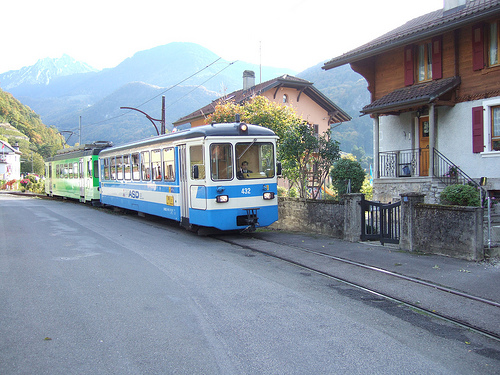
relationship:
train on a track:
[98, 121, 281, 232] [243, 228, 497, 346]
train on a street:
[98, 121, 281, 232] [0, 190, 499, 373]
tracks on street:
[226, 233, 498, 344] [0, 190, 499, 373]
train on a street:
[43, 121, 275, 233] [0, 190, 499, 373]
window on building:
[412, 36, 436, 84] [322, 0, 499, 260]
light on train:
[232, 110, 252, 134] [43, 121, 275, 233]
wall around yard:
[290, 197, 358, 239] [268, 134, 371, 224]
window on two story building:
[412, 36, 436, 84] [320, 0, 498, 265]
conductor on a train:
[237, 160, 254, 180] [43, 121, 275, 233]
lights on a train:
[211, 189, 281, 207] [43, 121, 275, 233]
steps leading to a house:
[435, 167, 497, 261] [319, 1, 499, 258]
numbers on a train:
[231, 183, 264, 196] [43, 121, 275, 233]